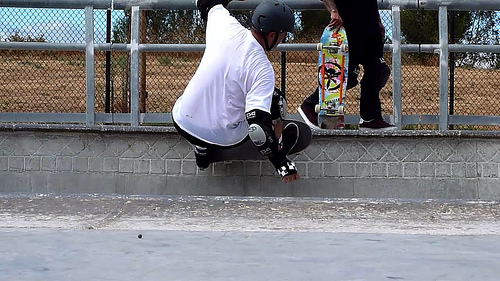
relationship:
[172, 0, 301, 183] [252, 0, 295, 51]
man wearing a helmet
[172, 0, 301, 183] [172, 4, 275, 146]
man wearing a shirt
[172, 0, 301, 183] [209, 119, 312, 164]
man does a trick on a skateboard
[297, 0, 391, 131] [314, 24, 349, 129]
person holding skateboard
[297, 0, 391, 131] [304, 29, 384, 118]
person wearing pants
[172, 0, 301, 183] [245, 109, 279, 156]
man wearing an elbow pad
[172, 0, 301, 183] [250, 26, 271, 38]
man has hair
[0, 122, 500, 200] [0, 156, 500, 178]
wall has a row of squares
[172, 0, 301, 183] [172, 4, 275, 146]
man has a shirt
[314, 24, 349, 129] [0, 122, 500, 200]
skateboard on top of wall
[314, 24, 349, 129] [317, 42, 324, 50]
skateboard has a wheel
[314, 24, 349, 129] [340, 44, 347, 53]
skateboard has a wheel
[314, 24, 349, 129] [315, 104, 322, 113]
skateboard has a wheel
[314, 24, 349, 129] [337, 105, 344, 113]
skateboard has a wheel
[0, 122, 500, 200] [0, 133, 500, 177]
wall has a design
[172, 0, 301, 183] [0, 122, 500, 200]
man on side of wall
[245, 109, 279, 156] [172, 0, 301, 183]
elbow pad on man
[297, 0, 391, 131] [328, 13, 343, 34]
person has a hand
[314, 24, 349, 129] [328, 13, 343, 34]
skateboard in hand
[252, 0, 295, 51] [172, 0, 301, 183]
helmet on man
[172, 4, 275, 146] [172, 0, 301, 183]
shirt on man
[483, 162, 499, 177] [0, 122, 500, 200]
square on wall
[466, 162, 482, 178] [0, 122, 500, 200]
square on wall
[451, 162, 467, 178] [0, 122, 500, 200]
square on wall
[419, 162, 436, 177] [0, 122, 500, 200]
square on wall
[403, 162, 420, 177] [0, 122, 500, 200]
square on wall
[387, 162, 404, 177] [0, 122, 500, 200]
square on wall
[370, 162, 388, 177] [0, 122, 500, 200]
square on wall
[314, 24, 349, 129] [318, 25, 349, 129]
skateboard has custom art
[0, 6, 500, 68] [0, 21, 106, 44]
sky has a cloudy area